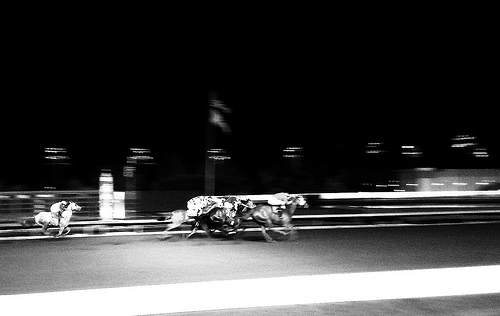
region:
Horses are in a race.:
[30, 192, 310, 242]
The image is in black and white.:
[1, 0, 496, 312]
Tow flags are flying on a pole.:
[206, 89, 231, 196]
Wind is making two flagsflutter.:
[207, 93, 232, 130]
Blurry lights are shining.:
[44, 135, 493, 160]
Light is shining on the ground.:
[0, 237, 499, 312]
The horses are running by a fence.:
[1, 192, 496, 240]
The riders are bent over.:
[46, 191, 293, 219]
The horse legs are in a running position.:
[37, 215, 302, 244]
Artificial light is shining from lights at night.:
[0, 0, 496, 189]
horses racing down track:
[18, 182, 347, 254]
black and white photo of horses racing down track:
[5, 6, 495, 314]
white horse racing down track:
[14, 190, 89, 247]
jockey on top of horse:
[40, 190, 69, 220]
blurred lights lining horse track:
[25, 136, 160, 176]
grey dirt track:
[12, 222, 491, 279]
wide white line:
[25, 253, 496, 315]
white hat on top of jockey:
[56, 198, 69, 208]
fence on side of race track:
[0, 183, 142, 235]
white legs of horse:
[52, 225, 76, 238]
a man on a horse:
[25, 188, 82, 240]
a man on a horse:
[174, 183, 249, 238]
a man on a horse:
[252, 184, 305, 246]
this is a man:
[273, 182, 297, 222]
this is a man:
[194, 173, 249, 225]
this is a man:
[44, 184, 72, 211]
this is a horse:
[26, 187, 83, 248]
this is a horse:
[179, 201, 254, 229]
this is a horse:
[239, 176, 339, 271]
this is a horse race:
[8, 161, 340, 251]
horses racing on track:
[135, 174, 327, 259]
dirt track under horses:
[238, 243, 328, 283]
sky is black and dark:
[222, 3, 356, 105]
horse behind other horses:
[11, 173, 132, 245]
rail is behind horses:
[0, 177, 114, 238]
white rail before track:
[71, 271, 395, 313]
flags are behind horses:
[184, 114, 251, 186]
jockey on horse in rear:
[48, 197, 69, 219]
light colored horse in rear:
[27, 187, 89, 252]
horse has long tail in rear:
[12, 208, 57, 230]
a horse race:
[16, 165, 326, 253]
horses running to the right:
[17, 180, 327, 245]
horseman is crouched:
[261, 185, 296, 210]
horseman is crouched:
[46, 195, 66, 215]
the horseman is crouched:
[183, 187, 210, 212]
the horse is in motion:
[20, 195, 85, 240]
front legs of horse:
[55, 221, 66, 241]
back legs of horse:
[36, 222, 51, 237]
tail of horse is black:
[18, 210, 38, 228]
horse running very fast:
[243, 188, 324, 248]